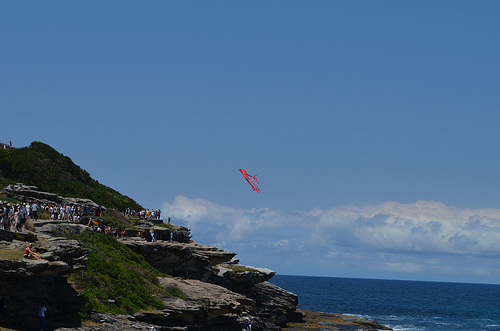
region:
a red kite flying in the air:
[238, 167, 263, 194]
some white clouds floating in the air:
[178, 195, 499, 281]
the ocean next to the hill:
[278, 273, 491, 329]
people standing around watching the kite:
[2, 196, 177, 243]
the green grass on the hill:
[68, 227, 188, 322]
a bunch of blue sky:
[50, 37, 467, 187]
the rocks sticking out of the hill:
[185, 235, 288, 316]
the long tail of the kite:
[247, 175, 258, 197]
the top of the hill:
[2, 137, 112, 199]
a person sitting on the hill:
[21, 239, 41, 271]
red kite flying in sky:
[229, 158, 273, 203]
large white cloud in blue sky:
[338, 181, 474, 268]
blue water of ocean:
[290, 271, 497, 325]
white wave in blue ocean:
[341, 310, 408, 330]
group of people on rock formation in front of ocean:
[3, 194, 179, 257]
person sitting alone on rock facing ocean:
[18, 238, 61, 267]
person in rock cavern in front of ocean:
[33, 296, 54, 328]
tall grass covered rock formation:
[1, 138, 172, 317]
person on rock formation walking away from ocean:
[144, 223, 161, 245]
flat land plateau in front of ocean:
[300, 300, 408, 327]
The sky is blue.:
[279, 55, 419, 145]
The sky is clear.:
[285, 68, 442, 165]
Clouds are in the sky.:
[314, 173, 426, 239]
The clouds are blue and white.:
[332, 177, 454, 234]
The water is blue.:
[397, 294, 473, 311]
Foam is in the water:
[402, 307, 492, 329]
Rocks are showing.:
[166, 247, 333, 322]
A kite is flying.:
[210, 150, 282, 220]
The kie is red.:
[223, 158, 283, 208]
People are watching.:
[0, 188, 192, 266]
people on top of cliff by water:
[0, 45, 414, 322]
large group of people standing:
[8, 201, 90, 223]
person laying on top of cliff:
[22, 228, 60, 290]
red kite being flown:
[220, 141, 282, 229]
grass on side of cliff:
[30, 247, 171, 329]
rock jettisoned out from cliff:
[187, 241, 318, 311]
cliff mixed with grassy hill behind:
[0, 70, 177, 308]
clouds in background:
[144, 177, 465, 304]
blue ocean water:
[330, 282, 434, 329]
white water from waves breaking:
[335, 294, 462, 329]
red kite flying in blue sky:
[231, 150, 271, 201]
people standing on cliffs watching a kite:
[0, 131, 300, 326]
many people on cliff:
[2, 173, 175, 328]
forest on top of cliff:
[0, 140, 125, 190]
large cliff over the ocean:
[195, 240, 400, 325]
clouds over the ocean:
[297, 191, 492, 306]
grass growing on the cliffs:
[77, 236, 177, 321]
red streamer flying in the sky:
[234, 161, 271, 208]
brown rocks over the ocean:
[302, 311, 385, 328]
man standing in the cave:
[17, 288, 62, 326]